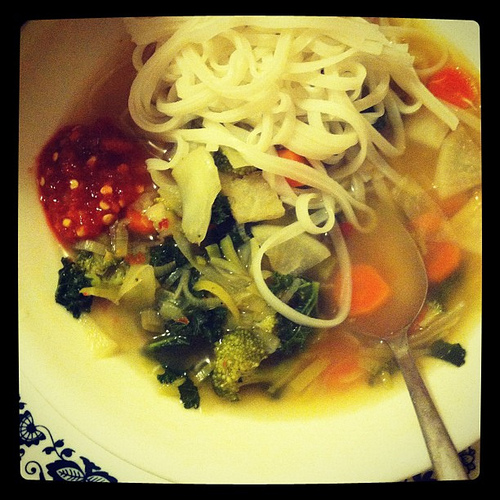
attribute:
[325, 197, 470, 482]
spoon — silver, metal, metallic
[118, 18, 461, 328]
noodles — white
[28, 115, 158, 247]
sauce — red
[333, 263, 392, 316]
carrot — orange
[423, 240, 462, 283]
carrot — orange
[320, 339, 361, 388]
carrot — orange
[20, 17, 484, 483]
bowl — white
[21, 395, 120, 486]
design — blue, black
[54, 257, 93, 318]
kale — green